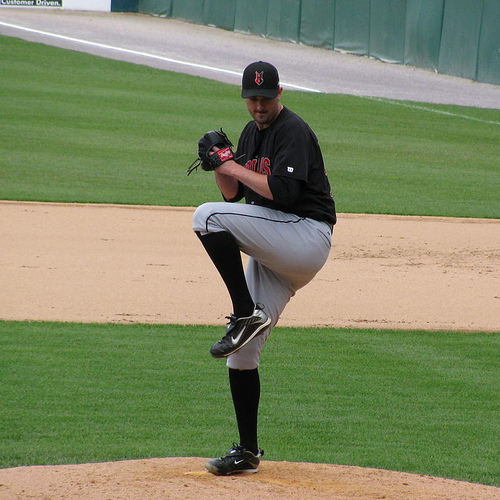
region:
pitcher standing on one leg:
[185, 60, 336, 474]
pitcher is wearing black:
[233, 105, 338, 232]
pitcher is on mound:
[0, 457, 499, 499]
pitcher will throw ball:
[190, 58, 337, 475]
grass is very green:
[2, 317, 499, 486]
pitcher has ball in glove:
[188, 127, 233, 175]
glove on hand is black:
[187, 127, 234, 177]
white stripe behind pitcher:
[1, 19, 499, 131]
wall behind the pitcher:
[0, 1, 499, 88]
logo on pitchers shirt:
[233, 154, 270, 175]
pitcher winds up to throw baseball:
[194, 58, 305, 465]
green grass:
[8, 322, 213, 453]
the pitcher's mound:
[6, 458, 498, 497]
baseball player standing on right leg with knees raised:
[198, 53, 330, 486]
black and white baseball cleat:
[202, 303, 269, 363]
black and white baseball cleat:
[210, 451, 270, 478]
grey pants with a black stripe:
[188, 198, 333, 378]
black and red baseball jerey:
[231, 113, 340, 223]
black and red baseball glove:
[189, 132, 239, 171]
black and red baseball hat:
[236, 58, 284, 99]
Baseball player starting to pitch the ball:
[184, 3, 382, 498]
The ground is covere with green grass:
[2, 33, 159, 200]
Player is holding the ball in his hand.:
[173, 53, 313, 209]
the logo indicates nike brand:
[191, 291, 329, 482]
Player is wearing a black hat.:
[197, 40, 324, 125]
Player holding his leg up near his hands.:
[185, 59, 384, 356]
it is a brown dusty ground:
[0, 201, 176, 319]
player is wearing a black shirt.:
[176, 46, 364, 378]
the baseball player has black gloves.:
[174, 101, 237, 206]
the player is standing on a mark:
[186, 461, 279, 498]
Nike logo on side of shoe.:
[225, 319, 256, 351]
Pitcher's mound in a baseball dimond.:
[25, 456, 469, 498]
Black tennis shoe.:
[206, 304, 281, 364]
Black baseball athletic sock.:
[204, 344, 282, 464]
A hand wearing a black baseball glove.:
[188, 125, 256, 176]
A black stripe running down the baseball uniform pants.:
[180, 198, 312, 236]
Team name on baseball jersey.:
[227, 153, 283, 185]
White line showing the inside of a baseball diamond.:
[26, 13, 494, 133]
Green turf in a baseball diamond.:
[43, 308, 468, 470]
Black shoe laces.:
[217, 308, 244, 329]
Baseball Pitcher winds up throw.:
[186, 53, 321, 335]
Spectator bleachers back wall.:
[289, 0, 497, 75]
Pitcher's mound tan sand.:
[2, 443, 497, 499]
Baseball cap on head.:
[214, 53, 304, 139]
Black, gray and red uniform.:
[226, 73, 324, 492]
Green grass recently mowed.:
[16, 60, 186, 192]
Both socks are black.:
[197, 236, 273, 460]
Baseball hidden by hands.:
[190, 128, 250, 178]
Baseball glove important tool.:
[184, 124, 251, 168]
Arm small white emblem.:
[270, 141, 310, 186]